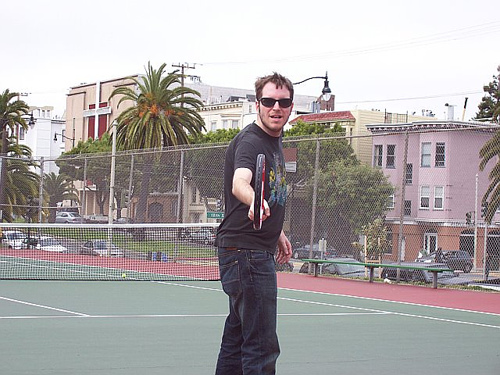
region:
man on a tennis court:
[208, 66, 310, 373]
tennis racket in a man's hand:
[249, 149, 271, 233]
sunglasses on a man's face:
[253, 93, 296, 109]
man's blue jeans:
[208, 243, 298, 374]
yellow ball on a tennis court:
[118, 270, 129, 281]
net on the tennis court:
[1, 213, 238, 294]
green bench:
[293, 249, 450, 292]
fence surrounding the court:
[1, 113, 498, 298]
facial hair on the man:
[256, 108, 297, 138]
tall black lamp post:
[270, 69, 342, 112]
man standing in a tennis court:
[216, 74, 294, 374]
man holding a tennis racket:
[248, 152, 273, 232]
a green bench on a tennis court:
[301, 258, 445, 290]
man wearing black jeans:
[216, 249, 277, 374]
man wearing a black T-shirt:
[216, 123, 286, 247]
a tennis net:
[0, 226, 222, 283]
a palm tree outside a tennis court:
[106, 68, 208, 243]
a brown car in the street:
[414, 248, 474, 273]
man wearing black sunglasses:
[256, 93, 293, 107]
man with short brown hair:
[255, 74, 295, 133]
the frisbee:
[244, 140, 273, 238]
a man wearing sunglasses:
[218, 67, 306, 373]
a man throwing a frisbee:
[223, 61, 308, 373]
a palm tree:
[113, 65, 203, 167]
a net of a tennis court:
[11, 219, 220, 297]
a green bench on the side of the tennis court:
[306, 253, 480, 299]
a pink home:
[358, 117, 488, 224]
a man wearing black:
[231, 75, 303, 373]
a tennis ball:
[113, 268, 138, 284]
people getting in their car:
[411, 240, 462, 273]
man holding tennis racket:
[206, 69, 300, 374]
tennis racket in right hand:
[241, 151, 272, 230]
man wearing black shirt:
[209, 120, 289, 258]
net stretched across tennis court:
[2, 218, 228, 292]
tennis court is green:
[0, 256, 496, 373]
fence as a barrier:
[1, 124, 496, 296]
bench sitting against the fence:
[302, 253, 446, 295]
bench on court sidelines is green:
[304, 255, 451, 288]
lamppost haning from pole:
[320, 68, 332, 103]